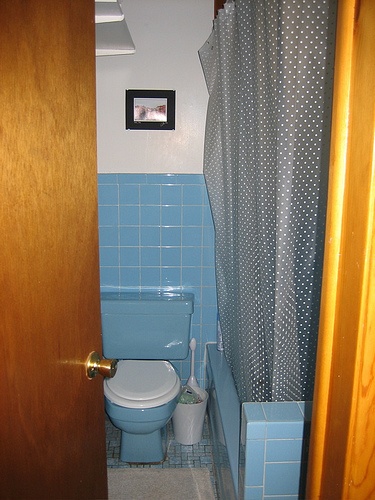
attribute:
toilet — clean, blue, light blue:
[96, 290, 194, 464]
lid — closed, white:
[103, 356, 180, 410]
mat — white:
[107, 468, 206, 500]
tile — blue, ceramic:
[99, 172, 196, 290]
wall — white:
[123, 0, 213, 293]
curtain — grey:
[200, 0, 331, 397]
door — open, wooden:
[0, 0, 108, 497]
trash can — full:
[172, 384, 207, 445]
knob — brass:
[85, 350, 118, 380]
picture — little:
[125, 88, 175, 130]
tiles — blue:
[263, 402, 304, 498]